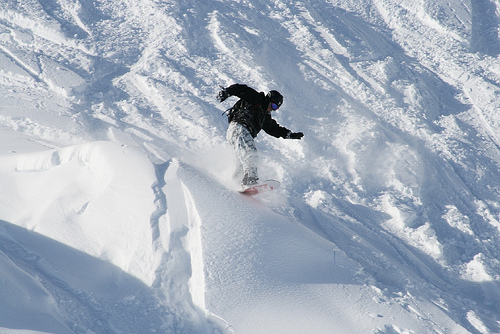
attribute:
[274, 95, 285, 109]
goggles — blue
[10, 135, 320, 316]
mound — small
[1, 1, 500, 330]
snow — white, plentiful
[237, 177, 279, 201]
snowboard — red, white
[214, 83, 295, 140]
jacket — black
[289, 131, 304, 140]
glove — black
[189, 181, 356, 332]
snow — undisturbed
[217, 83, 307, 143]
arms — out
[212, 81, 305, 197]
person — snowboarding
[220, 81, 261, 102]
sleeves — long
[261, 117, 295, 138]
sleeves — long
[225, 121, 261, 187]
pants — light, checkered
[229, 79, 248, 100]
elbow — bent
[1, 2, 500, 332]
mountain — steep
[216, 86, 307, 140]
gloves — black